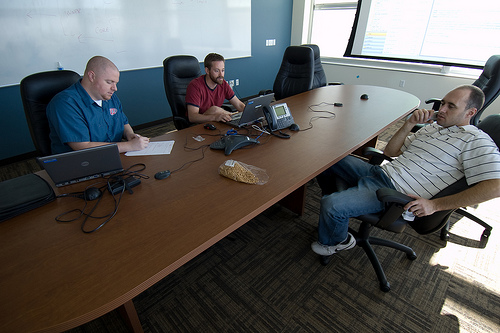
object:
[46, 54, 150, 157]
person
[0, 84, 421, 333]
table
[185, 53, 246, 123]
person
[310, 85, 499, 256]
person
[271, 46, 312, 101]
chair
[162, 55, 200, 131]
chair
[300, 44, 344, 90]
chair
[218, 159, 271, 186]
bag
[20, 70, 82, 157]
chair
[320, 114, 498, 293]
chair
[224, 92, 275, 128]
laptop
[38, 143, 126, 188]
laptop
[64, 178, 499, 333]
floor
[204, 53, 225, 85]
head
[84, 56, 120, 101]
head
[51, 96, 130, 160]
arm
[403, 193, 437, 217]
hand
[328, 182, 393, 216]
thigh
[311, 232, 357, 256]
foot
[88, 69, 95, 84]
ear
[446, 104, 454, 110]
eye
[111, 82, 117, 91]
nose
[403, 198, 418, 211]
fingers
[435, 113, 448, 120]
mouth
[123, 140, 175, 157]
paper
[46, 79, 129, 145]
shirt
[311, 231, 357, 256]
sneaker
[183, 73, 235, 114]
shirt